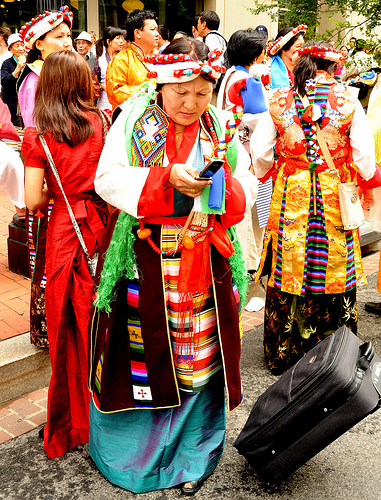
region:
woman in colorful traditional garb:
[90, 38, 246, 497]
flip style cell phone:
[200, 157, 225, 183]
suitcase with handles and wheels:
[235, 325, 379, 478]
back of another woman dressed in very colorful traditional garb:
[258, 41, 358, 372]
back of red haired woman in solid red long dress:
[25, 51, 110, 457]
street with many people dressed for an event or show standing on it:
[1, 269, 379, 497]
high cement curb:
[0, 336, 46, 403]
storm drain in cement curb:
[361, 229, 379, 271]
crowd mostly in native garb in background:
[7, 10, 378, 135]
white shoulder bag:
[339, 177, 365, 238]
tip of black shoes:
[163, 468, 209, 498]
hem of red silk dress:
[24, 399, 105, 449]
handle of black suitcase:
[350, 328, 378, 366]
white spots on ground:
[23, 473, 95, 492]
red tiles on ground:
[3, 402, 39, 440]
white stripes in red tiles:
[11, 403, 41, 435]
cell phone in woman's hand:
[174, 151, 272, 199]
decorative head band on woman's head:
[144, 35, 235, 88]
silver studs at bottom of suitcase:
[303, 399, 362, 430]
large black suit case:
[241, 321, 373, 475]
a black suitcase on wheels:
[241, 323, 379, 485]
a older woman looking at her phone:
[112, 34, 226, 195]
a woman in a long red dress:
[20, 48, 108, 414]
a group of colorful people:
[15, 7, 376, 329]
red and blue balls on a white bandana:
[140, 43, 232, 97]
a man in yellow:
[105, 7, 159, 90]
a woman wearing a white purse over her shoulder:
[273, 41, 372, 253]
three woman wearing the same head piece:
[152, 21, 365, 104]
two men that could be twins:
[5, 26, 95, 67]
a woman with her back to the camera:
[17, 43, 137, 313]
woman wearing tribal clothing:
[123, 23, 253, 406]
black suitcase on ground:
[223, 317, 379, 491]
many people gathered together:
[7, 18, 371, 399]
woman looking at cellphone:
[118, 44, 253, 182]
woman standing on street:
[5, 315, 241, 494]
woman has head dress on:
[131, 37, 246, 302]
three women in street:
[23, 72, 350, 431]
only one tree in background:
[214, 0, 377, 113]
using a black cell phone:
[151, 139, 239, 220]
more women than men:
[22, 13, 331, 224]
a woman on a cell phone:
[138, 51, 257, 232]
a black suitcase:
[223, 294, 373, 498]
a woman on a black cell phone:
[75, 15, 255, 213]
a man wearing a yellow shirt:
[101, 1, 184, 125]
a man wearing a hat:
[5, 32, 51, 105]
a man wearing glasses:
[60, 25, 118, 101]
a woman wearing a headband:
[105, 32, 259, 190]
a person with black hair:
[218, 23, 283, 105]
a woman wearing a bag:
[272, 14, 371, 242]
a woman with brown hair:
[17, 40, 128, 217]